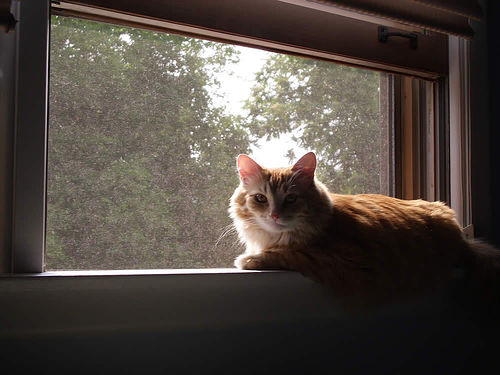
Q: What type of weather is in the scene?
A: It is clear.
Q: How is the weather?
A: It is clear.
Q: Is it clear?
A: Yes, it is clear.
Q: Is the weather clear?
A: Yes, it is clear.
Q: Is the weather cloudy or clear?
A: It is clear.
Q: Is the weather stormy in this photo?
A: No, it is clear.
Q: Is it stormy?
A: No, it is clear.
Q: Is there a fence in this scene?
A: No, there are no fences.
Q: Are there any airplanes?
A: No, there are no airplanes.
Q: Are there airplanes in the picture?
A: No, there are no airplanes.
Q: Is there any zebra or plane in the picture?
A: No, there are no airplanes or zebras.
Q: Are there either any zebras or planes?
A: No, there are no planes or zebras.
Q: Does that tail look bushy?
A: Yes, the tail is bushy.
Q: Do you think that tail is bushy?
A: Yes, the tail is bushy.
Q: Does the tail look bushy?
A: Yes, the tail is bushy.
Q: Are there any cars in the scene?
A: No, there are no cars.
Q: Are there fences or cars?
A: No, there are no cars or fences.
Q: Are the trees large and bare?
A: No, the trees are large but leafy.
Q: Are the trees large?
A: Yes, the trees are large.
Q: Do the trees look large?
A: Yes, the trees are large.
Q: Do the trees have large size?
A: Yes, the trees are large.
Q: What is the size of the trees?
A: The trees are large.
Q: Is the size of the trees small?
A: No, the trees are large.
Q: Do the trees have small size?
A: No, the trees are large.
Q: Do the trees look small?
A: No, the trees are large.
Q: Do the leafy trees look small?
A: No, the trees are large.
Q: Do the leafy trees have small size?
A: No, the trees are large.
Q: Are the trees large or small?
A: The trees are large.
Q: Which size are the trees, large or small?
A: The trees are large.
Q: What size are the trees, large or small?
A: The trees are large.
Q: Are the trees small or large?
A: The trees are large.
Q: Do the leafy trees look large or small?
A: The trees are large.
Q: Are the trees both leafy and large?
A: Yes, the trees are leafy and large.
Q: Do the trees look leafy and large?
A: Yes, the trees are leafy and large.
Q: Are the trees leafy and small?
A: No, the trees are leafy but large.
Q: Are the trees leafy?
A: Yes, the trees are leafy.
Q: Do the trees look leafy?
A: Yes, the trees are leafy.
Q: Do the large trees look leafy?
A: Yes, the trees are leafy.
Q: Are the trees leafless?
A: No, the trees are leafy.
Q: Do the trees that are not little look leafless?
A: No, the trees are leafy.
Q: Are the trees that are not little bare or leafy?
A: The trees are leafy.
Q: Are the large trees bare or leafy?
A: The trees are leafy.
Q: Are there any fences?
A: No, there are no fences.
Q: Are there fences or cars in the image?
A: No, there are no fences or cars.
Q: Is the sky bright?
A: Yes, the sky is bright.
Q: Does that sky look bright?
A: Yes, the sky is bright.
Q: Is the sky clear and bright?
A: Yes, the sky is clear and bright.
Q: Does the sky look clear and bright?
A: Yes, the sky is clear and bright.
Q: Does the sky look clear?
A: Yes, the sky is clear.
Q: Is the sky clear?
A: Yes, the sky is clear.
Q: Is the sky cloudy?
A: No, the sky is clear.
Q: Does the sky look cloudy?
A: No, the sky is clear.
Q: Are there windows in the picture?
A: Yes, there is a window.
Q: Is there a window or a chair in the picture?
A: Yes, there is a window.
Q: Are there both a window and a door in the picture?
A: No, there is a window but no doors.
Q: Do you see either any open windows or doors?
A: Yes, there is an open window.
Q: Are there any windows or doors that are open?
A: Yes, the window is open.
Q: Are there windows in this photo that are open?
A: Yes, there is an open window.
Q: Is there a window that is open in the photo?
A: Yes, there is an open window.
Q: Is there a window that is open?
A: Yes, there is a window that is open.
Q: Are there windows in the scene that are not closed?
A: Yes, there is a open window.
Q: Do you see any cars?
A: No, there are no cars.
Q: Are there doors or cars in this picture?
A: No, there are no cars or doors.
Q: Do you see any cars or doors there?
A: No, there are no cars or doors.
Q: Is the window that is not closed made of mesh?
A: Yes, the window is made of mesh.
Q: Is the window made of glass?
A: No, the window is made of mesh.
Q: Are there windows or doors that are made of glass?
A: No, there is a window but it is made of mesh.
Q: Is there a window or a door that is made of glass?
A: No, there is a window but it is made of mesh.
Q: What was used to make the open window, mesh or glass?
A: The window is made of mesh.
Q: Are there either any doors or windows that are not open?
A: No, there is a window but it is open.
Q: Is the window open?
A: Yes, the window is open.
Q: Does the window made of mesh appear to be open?
A: Yes, the window is open.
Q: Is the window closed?
A: No, the window is open.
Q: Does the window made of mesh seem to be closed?
A: No, the window is open.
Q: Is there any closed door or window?
A: No, there is a window but it is open.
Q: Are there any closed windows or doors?
A: No, there is a window but it is open.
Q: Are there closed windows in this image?
A: No, there is a window but it is open.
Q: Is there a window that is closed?
A: No, there is a window but it is open.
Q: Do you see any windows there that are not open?
A: No, there is a window but it is open.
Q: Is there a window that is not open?
A: No, there is a window but it is open.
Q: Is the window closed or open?
A: The window is open.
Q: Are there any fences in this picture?
A: No, there are no fences.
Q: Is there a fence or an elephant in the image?
A: No, there are no fences or elephants.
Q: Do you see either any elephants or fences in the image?
A: No, there are no fences or elephants.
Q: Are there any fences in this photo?
A: No, there are no fences.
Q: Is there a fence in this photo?
A: No, there are no fences.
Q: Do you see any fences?
A: No, there are no fences.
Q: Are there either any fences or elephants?
A: No, there are no fences or elephants.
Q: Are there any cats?
A: Yes, there is a cat.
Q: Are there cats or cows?
A: Yes, there is a cat.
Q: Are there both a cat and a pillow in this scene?
A: No, there is a cat but no pillows.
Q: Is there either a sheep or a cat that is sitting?
A: Yes, the cat is sitting.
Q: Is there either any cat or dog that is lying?
A: Yes, the cat is lying.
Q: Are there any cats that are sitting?
A: Yes, there is a cat that is sitting.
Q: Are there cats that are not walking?
A: Yes, there is a cat that is sitting.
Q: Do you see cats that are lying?
A: Yes, there is a cat that is lying.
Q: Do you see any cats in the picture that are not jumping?
A: Yes, there is a cat that is lying .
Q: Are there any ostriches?
A: No, there are no ostriches.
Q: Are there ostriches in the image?
A: No, there are no ostriches.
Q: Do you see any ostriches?
A: No, there are no ostriches.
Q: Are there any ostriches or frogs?
A: No, there are no ostriches or frogs.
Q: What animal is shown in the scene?
A: The animal is a cat.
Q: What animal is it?
A: The animal is a cat.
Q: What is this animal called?
A: That is a cat.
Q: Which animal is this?
A: That is a cat.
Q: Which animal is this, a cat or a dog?
A: That is a cat.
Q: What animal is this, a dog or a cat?
A: That is a cat.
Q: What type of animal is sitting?
A: The animal is a cat.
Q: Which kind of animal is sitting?
A: The animal is a cat.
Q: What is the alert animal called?
A: The animal is a cat.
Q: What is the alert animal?
A: The animal is a cat.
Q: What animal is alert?
A: The animal is a cat.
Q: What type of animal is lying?
A: The animal is a cat.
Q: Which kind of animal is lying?
A: The animal is a cat.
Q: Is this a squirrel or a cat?
A: This is a cat.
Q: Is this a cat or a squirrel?
A: This is a cat.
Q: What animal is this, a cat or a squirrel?
A: This is a cat.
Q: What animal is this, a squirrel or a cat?
A: This is a cat.